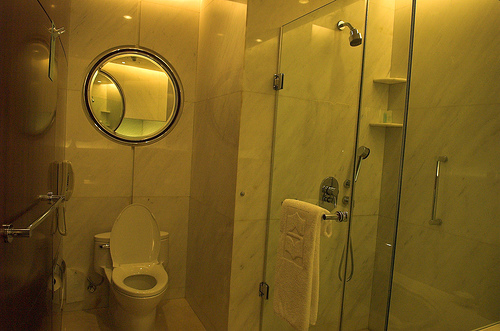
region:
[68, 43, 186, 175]
this is a mirror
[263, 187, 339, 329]
this is a towel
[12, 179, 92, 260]
this is a towel rack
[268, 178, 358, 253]
a used towel rack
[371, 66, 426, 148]
these are two shelves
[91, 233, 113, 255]
this is a flusher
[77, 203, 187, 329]
this is a toilet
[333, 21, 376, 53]
this is a shower head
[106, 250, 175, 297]
this is a toilet seat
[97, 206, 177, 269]
this is a toilet lid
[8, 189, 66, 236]
A silver towel rack.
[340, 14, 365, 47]
A silver shower head.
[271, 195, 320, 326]
A white towel hanging.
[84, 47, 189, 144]
A round mirror.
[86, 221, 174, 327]
A white toilet.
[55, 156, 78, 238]
A corded white telephone.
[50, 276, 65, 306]
A white roll of toilet paper.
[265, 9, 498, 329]
A stand up shower.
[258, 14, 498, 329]
Glass shower doors.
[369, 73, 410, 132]
Two shelves in a shower.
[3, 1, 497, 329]
A bathroom scene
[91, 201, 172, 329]
A commode is in the bathroom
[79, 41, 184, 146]
A mirror is on the wall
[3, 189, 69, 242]
A towel rack is on the wall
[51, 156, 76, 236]
A telephone is hanging on the wall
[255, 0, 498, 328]
This is a shower stall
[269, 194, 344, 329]
A towel is hanging on the shower door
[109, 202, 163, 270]
The commode's lid is up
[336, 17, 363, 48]
The shower nozzle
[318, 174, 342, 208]
This is the shower's control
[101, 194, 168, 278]
THE TOILET LID IS UP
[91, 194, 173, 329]
THE TOILET IS WHITE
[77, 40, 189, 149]
THE MIRROR IS ROUND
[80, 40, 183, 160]
THE MIRROR IS ABOVE THE TOILET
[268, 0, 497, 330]
THE SHOWER DOOR IS GLASS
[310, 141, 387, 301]
THE FAUCET IS ON THE WALL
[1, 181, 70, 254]
THE SAFETY HANDLE IS ON THE WALL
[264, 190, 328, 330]
THE TOWEL IS WHITE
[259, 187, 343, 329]
THE TOWEL IS HANGING ON THE DOOR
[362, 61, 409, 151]
THE SHELF IS IN THE CORNER OF THE SHOWER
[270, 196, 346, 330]
A white bath towel hanging over a metal rack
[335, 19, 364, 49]
A silver shower head fixed to a wall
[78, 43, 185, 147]
A round framed two view mirror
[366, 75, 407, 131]
Shower corner storage shelves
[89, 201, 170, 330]
A white shiny porcelain toilet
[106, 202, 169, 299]
A toilet seat with the lid up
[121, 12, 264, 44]
Light reflections off marble tiles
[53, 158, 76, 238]
A wall mounted phone with a cord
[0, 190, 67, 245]
A silver towel rack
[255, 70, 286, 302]
Wall mounted brackets attaching glass shower door